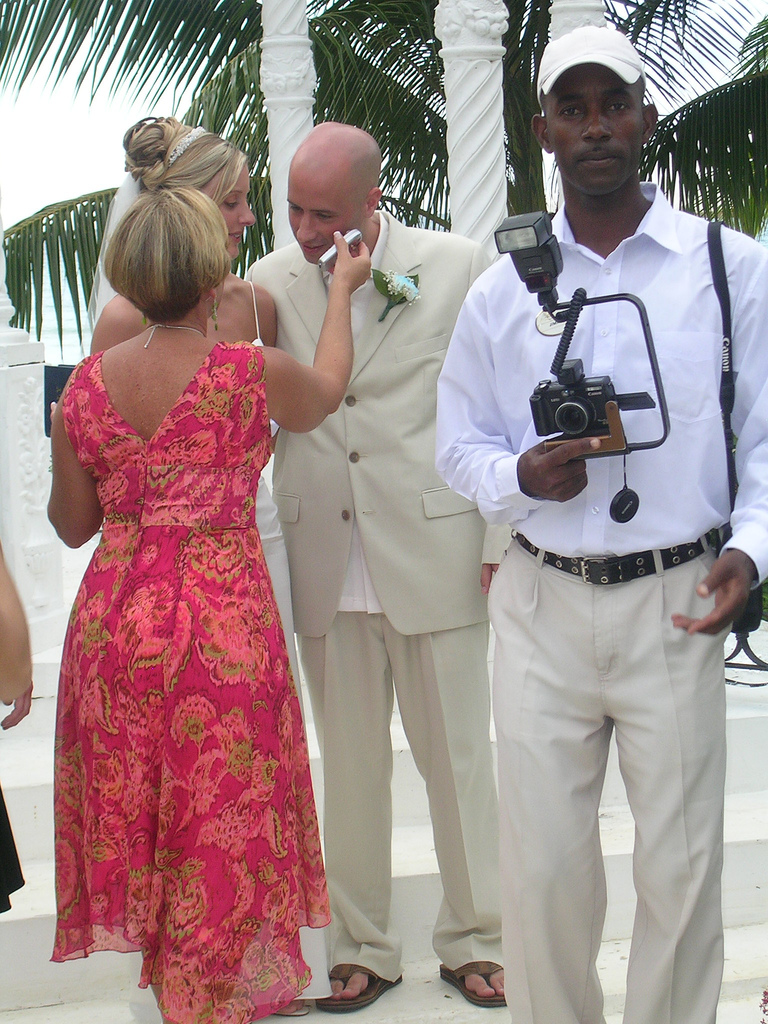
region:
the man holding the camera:
[434, 23, 766, 1019]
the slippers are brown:
[315, 961, 507, 1013]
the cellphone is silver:
[319, 228, 361, 267]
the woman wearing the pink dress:
[48, 188, 370, 1022]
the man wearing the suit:
[245, 120, 509, 1015]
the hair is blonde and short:
[102, 185, 231, 319]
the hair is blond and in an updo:
[120, 115, 250, 211]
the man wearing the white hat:
[436, 23, 766, 1020]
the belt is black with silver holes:
[513, 525, 710, 583]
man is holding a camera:
[427, 16, 767, 1020]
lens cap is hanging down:
[605, 451, 646, 536]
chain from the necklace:
[132, 318, 171, 360]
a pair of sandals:
[319, 953, 513, 1006]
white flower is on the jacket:
[369, 248, 423, 335]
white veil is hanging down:
[92, 162, 155, 333]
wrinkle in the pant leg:
[662, 852, 721, 980]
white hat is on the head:
[533, 13, 654, 106]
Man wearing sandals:
[317, 946, 522, 1018]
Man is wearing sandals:
[299, 949, 545, 1022]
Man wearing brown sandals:
[306, 944, 533, 1019]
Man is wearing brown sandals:
[313, 934, 521, 1017]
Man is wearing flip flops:
[312, 949, 516, 1018]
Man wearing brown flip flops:
[314, 951, 535, 1011]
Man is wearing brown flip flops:
[302, 951, 521, 1016]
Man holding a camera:
[479, 178, 694, 521]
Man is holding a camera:
[481, 179, 687, 535]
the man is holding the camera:
[489, 365, 652, 497]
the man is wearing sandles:
[315, 941, 522, 1011]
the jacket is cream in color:
[374, 354, 426, 411]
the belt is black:
[619, 545, 685, 581]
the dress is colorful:
[150, 528, 235, 602]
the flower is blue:
[385, 266, 423, 304]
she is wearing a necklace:
[150, 319, 188, 339]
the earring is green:
[209, 296, 225, 331]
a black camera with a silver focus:
[529, 359, 656, 437]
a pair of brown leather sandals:
[315, 958, 508, 1011]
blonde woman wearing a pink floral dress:
[50, 185, 329, 1023]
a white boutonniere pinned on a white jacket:
[249, 211, 490, 638]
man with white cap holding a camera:
[436, 26, 766, 1021]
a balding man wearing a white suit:
[245, 121, 491, 1010]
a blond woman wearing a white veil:
[92, 113, 302, 725]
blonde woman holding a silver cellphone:
[48, 185, 372, 1013]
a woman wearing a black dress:
[0, 551, 32, 914]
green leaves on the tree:
[356, 78, 398, 144]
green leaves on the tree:
[20, 206, 60, 259]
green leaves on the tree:
[62, 186, 96, 246]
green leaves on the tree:
[402, 147, 427, 183]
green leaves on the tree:
[404, 147, 448, 222]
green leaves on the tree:
[720, 149, 760, 248]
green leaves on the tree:
[689, 67, 732, 165]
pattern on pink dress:
[258, 879, 296, 930]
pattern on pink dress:
[206, 856, 258, 929]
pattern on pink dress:
[153, 856, 208, 945]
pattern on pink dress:
[82, 885, 117, 913]